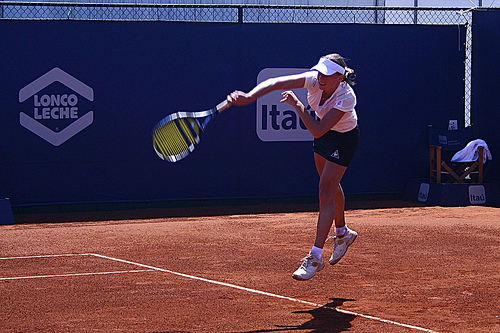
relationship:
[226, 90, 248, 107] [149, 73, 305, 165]
hand doing backhand swing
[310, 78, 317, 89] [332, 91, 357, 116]
logo on sleeve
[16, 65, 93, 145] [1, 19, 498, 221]
logo printed on barrier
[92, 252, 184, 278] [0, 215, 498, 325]
line painted on tennis courts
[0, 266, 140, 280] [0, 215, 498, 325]
line painted on tennis courts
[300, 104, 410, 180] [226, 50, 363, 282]
black shorts are on person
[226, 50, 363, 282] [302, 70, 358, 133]
person wearing shirt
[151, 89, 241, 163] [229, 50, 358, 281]
racket in player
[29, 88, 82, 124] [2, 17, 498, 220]
word in wall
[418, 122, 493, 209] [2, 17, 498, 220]
chair against wall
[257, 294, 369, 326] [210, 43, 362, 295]
shadow cast by female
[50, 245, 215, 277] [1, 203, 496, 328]
lines on pavement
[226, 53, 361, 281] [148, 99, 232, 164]
woman holding tennis rack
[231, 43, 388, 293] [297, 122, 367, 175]
woman wearing a skirt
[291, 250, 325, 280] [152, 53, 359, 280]
left shoe of tennis player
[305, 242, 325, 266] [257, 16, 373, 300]
sock of player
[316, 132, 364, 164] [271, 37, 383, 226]
shorts of woman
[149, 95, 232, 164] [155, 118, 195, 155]
tennis racket with net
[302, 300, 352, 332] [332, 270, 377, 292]
shadow on ground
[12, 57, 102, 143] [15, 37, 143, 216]
logo on side of wall